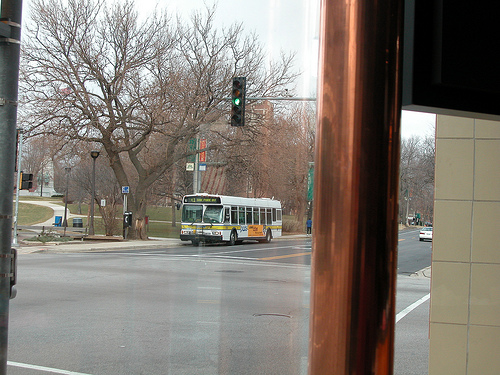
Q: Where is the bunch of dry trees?
A: Next to the bus.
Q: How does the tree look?
A: Leafless.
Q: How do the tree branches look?
A: Leafless.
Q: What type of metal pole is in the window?
A: Copper.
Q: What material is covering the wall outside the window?
A: Tile.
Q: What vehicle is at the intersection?
A: City bus.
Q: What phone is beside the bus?
A: Payphone.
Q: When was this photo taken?
A: Daytime.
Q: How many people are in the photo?
A: Zero.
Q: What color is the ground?
A: Grey.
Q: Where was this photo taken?
A: Looking out window to the street.